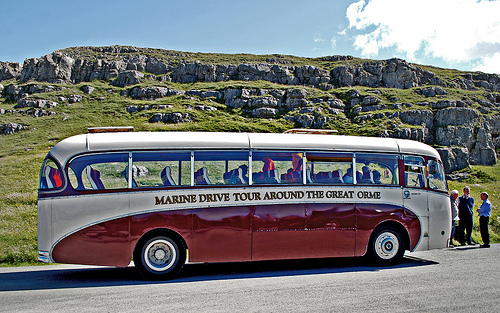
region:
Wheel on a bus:
[133, 231, 188, 278]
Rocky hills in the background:
[3, 48, 493, 181]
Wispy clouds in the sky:
[318, 0, 438, 57]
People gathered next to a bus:
[448, 177, 493, 250]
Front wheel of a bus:
[369, 225, 406, 261]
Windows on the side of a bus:
[65, 141, 450, 194]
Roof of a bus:
[52, 116, 442, 157]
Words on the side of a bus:
[154, 189, 381, 205]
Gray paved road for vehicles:
[3, 243, 498, 310]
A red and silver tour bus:
[34, 127, 454, 279]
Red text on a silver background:
[152, 188, 385, 207]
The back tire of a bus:
[134, 229, 187, 279]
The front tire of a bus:
[370, 226, 405, 266]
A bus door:
[400, 155, 430, 252]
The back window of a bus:
[37, 151, 67, 193]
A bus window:
[134, 150, 193, 186]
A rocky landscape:
[3, 42, 499, 264]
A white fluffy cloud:
[312, 2, 499, 73]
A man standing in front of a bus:
[448, 187, 460, 249]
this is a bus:
[31, 87, 470, 297]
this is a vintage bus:
[19, 96, 467, 285]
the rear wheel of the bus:
[127, 228, 187, 277]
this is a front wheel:
[364, 208, 424, 271]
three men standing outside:
[439, 173, 498, 271]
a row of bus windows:
[66, 145, 418, 192]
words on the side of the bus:
[148, 186, 388, 212]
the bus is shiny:
[25, 103, 472, 294]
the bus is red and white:
[15, 105, 463, 279]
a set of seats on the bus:
[80, 163, 118, 188]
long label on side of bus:
[145, 179, 385, 214]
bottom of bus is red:
[42, 197, 430, 282]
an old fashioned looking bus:
[35, 121, 458, 272]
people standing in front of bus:
[445, 179, 495, 252]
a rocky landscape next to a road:
[5, 38, 497, 183]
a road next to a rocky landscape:
[4, 228, 498, 310]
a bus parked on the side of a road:
[33, 120, 459, 274]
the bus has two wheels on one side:
[135, 218, 415, 276]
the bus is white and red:
[31, 121, 460, 267]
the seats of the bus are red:
[28, 153, 393, 190]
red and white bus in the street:
[36, 138, 450, 266]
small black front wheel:
[136, 227, 187, 275]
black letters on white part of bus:
[149, 187, 383, 206]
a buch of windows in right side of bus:
[66, 152, 447, 195]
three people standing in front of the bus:
[446, 187, 491, 249]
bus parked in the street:
[36, 131, 451, 269]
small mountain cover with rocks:
[0, 51, 491, 255]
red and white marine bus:
[31, 132, 450, 270]